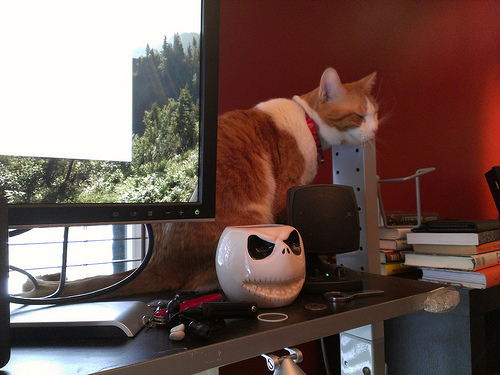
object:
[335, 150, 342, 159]
hole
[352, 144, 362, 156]
hole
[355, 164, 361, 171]
hole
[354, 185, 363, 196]
hole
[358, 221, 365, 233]
hole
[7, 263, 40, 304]
cords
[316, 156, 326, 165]
bell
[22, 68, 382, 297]
cat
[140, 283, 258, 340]
knife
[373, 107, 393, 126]
whiskers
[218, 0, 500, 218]
wall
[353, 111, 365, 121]
eye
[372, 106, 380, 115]
eye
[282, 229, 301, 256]
eye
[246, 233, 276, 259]
eye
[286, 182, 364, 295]
speaker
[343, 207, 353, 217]
knob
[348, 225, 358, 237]
knob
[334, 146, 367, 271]
holes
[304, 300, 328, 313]
quarter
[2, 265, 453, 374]
shelf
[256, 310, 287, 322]
hair band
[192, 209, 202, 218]
power button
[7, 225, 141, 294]
light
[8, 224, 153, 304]
window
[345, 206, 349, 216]
light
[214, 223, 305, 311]
bowl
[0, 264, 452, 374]
desk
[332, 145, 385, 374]
pole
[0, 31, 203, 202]
scene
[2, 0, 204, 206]
monitor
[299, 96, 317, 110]
cat neck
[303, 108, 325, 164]
collar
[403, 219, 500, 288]
books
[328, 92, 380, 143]
cat face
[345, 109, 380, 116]
eyes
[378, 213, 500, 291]
books